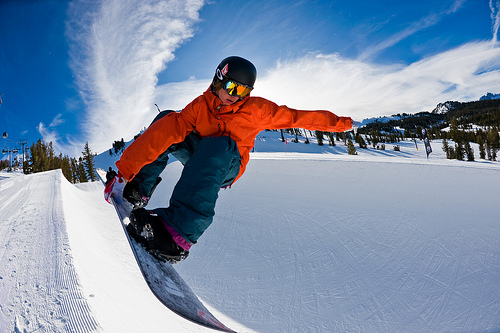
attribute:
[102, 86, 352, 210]
jacket — orange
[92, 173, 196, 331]
board — long, snowboard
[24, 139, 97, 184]
trees — leafy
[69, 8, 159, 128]
cloud — white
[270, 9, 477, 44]
sky — blue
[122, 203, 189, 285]
boots — black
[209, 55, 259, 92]
helmet — black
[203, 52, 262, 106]
helmet — black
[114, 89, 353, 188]
jacket — orange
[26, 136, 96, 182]
trees — tall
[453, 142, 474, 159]
leaves — green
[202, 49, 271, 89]
helmet — black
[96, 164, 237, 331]
snowboard — black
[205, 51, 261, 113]
head — person's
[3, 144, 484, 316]
snow — white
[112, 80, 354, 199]
jacket — orange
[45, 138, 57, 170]
tree — green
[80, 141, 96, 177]
tree — green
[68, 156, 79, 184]
tree — green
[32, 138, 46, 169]
tree — green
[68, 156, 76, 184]
tree — green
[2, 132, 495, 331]
snow — white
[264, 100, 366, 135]
arm — stretched out